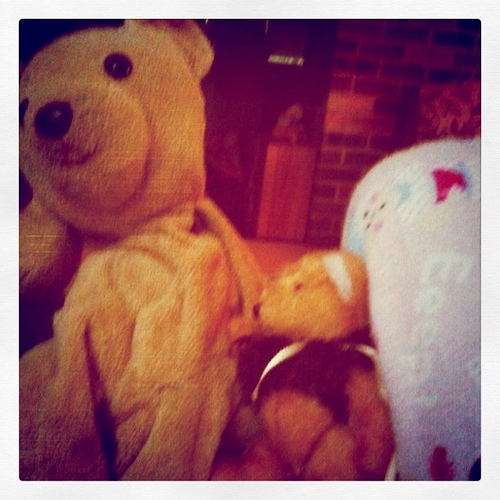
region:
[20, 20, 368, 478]
a floppy brown teddy bear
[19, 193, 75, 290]
a teddy bear arm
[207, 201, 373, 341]
a teddy bear arm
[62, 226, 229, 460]
the body of a teddy bear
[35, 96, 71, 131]
the black nose of a teddy bear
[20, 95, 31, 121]
the black eye of a teddy bear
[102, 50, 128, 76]
the black eye of a teddy bear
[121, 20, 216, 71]
the ear a teddy bear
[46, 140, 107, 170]
the smile of the bear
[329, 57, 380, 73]
a red brick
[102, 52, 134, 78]
A large round teddy bear eye.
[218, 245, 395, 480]
A small brown teddy bear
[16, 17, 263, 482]
Large brown teddy bear on the left.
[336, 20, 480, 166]
Top of a brick wall.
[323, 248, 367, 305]
Brown and white ear of a smaller teddy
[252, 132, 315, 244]
The side of a large wooden speaker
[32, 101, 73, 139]
Large black nose of a teddy bear.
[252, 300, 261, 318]
Little black nose on a small brown bear.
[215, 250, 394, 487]
Small brown bear beside a larger bear.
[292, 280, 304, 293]
Small black eye on a small teddy bear.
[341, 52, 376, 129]
this is the wall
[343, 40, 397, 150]
the wall is made of bricks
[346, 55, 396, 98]
the bricks are small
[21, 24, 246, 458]
this is a teddy bear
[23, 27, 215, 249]
the teddy bear is big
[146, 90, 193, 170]
the teddy bear is brown in color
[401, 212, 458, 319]
this is a cloth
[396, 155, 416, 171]
the cloth is blue in color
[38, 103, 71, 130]
the nose is big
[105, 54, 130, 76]
the eye is black in color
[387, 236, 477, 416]
'eeep!' in white flannel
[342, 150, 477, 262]
a baby, animal or human, wearing red+blue, beside 'eeep!', all on pink flannel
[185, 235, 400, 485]
small bear in the middle, jointed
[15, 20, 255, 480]
large bear on right, wearing wistful expression &, perhaps, towel as napkin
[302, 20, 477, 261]
brick wall in background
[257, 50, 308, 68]
illegible sign, in white, up top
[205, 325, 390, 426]
small bear wears thin white satin ribbon, potential huge black bow tie [?]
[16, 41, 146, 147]
large bear has round encircled dark eyes, dark nose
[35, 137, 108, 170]
large bear w/ contemplative small smile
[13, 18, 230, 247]
large bear has rounded ear, double chin, head atilt to its right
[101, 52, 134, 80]
Black eye of a teddy bear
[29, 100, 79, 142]
Black nose of a stuffed bear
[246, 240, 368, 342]
Head of stuffed bear looking left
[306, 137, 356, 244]
Red bricks in a wall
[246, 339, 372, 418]
Dark shirt worn by a stuffed bear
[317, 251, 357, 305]
White in the ear of a stuffed bear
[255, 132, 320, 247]
Wooden box on a fireplace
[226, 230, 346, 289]
Wooden footer block on a fireplace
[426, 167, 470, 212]
Red bow on a white pillow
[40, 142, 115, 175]
Smile on a bear's face